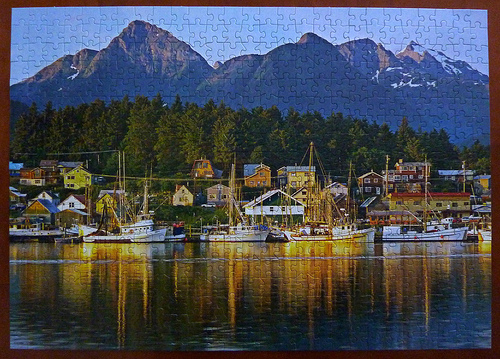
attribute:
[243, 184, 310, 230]
boathouse — green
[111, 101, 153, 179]
tree — thick, growing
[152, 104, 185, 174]
tree — thick, growing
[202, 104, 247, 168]
tree — thick, growing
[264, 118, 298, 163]
tree — thick, growing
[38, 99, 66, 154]
tree — thick, growing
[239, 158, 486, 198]
houses — small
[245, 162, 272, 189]
home — two story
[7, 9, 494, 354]
puzzle — jigsaw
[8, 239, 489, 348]
lights — reflecting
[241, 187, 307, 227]
trim — white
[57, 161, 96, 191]
building — small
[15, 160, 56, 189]
building — small